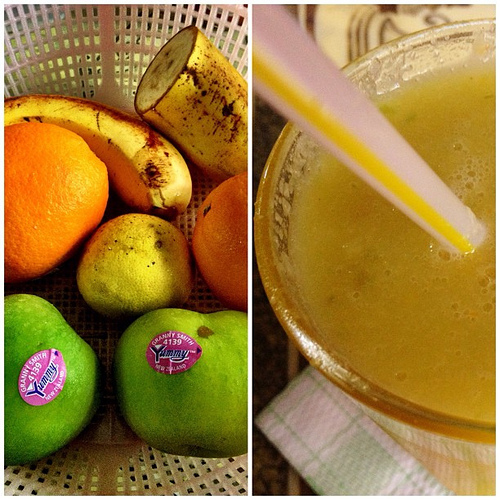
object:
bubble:
[287, 47, 499, 423]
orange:
[0, 128, 108, 279]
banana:
[134, 27, 253, 183]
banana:
[1, 87, 190, 215]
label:
[146, 330, 201, 372]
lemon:
[74, 212, 193, 318]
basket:
[6, 6, 246, 496]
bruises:
[101, 215, 173, 253]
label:
[17, 347, 68, 407]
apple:
[117, 303, 246, 459]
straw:
[253, 0, 485, 258]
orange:
[192, 170, 249, 315]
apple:
[3, 293, 103, 471]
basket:
[0, 0, 246, 499]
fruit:
[0, 25, 251, 466]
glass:
[251, 20, 496, 437]